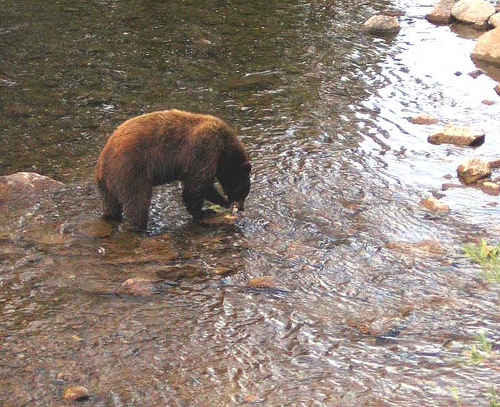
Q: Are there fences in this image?
A: No, there are no fences.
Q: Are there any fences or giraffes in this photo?
A: No, there are no fences or giraffes.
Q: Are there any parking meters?
A: No, there are no parking meters.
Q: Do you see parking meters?
A: No, there are no parking meters.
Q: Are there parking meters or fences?
A: No, there are no parking meters or fences.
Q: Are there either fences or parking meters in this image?
A: No, there are no parking meters or fences.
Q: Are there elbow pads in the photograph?
A: No, there are no elbow pads.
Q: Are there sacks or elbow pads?
A: No, there are no elbow pads or sacks.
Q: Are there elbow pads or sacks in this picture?
A: No, there are no elbow pads or sacks.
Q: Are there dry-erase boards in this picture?
A: No, there are no dry-erase boards.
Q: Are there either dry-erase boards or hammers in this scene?
A: No, there are no dry-erase boards or hammers.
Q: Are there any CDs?
A: No, there are no cds.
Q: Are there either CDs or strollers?
A: No, there are no CDs or strollers.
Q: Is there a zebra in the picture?
A: No, there are no zebras.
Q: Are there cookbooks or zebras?
A: No, there are no zebras or cookbooks.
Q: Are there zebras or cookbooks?
A: No, there are no zebras or cookbooks.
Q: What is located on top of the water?
A: The rock is on top of the water.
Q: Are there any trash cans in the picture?
A: No, there are no trash cans.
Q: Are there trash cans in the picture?
A: No, there are no trash cans.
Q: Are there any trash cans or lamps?
A: No, there are no trash cans or lamps.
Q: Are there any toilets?
A: No, there are no toilets.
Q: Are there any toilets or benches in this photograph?
A: No, there are no toilets or benches.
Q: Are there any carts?
A: No, there are no carts.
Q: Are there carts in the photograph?
A: No, there are no carts.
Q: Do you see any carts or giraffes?
A: No, there are no carts or giraffes.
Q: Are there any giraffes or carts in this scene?
A: No, there are no carts or giraffes.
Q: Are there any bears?
A: Yes, there is a bear.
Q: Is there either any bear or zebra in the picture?
A: Yes, there is a bear.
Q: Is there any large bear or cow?
A: Yes, there is a large bear.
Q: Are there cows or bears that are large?
A: Yes, the bear is large.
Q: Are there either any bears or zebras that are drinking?
A: Yes, the bear is drinking.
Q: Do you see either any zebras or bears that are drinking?
A: Yes, the bear is drinking.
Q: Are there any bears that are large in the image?
A: Yes, there is a large bear.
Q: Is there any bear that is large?
A: Yes, there is a bear that is large.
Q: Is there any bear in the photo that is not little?
A: Yes, there is a large bear.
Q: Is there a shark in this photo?
A: No, there are no sharks.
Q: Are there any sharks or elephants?
A: No, there are no sharks or elephants.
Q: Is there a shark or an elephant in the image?
A: No, there are no sharks or elephants.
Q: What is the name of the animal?
A: The animal is a bear.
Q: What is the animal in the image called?
A: The animal is a bear.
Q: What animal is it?
A: The animal is a bear.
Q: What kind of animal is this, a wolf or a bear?
A: This is a bear.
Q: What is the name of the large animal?
A: The animal is a bear.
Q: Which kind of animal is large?
A: The animal is a bear.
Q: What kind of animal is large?
A: The animal is a bear.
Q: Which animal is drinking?
A: The animal is a bear.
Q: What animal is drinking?
A: The animal is a bear.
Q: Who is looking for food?
A: The bear is looking for food.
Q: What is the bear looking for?
A: The bear is looking for food.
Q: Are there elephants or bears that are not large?
A: No, there is a bear but it is large.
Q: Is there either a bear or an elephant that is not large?
A: No, there is a bear but it is large.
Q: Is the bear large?
A: Yes, the bear is large.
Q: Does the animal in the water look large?
A: Yes, the bear is large.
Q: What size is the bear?
A: The bear is large.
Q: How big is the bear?
A: The bear is large.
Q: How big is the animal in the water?
A: The bear is large.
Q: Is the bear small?
A: No, the bear is large.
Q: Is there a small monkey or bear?
A: No, there is a bear but it is large.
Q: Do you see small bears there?
A: No, there is a bear but it is large.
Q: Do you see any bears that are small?
A: No, there is a bear but it is large.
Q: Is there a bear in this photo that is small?
A: No, there is a bear but it is large.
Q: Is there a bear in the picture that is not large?
A: No, there is a bear but it is large.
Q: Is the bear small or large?
A: The bear is large.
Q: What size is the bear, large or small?
A: The bear is large.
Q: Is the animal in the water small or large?
A: The bear is large.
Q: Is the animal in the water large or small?
A: The bear is large.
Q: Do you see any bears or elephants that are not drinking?
A: No, there is a bear but it is drinking.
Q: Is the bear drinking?
A: Yes, the bear is drinking.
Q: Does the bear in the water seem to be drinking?
A: Yes, the bear is drinking.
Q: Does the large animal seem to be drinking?
A: Yes, the bear is drinking.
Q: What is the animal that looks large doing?
A: The bear is drinking.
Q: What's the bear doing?
A: The bear is drinking.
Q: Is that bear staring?
A: No, the bear is drinking.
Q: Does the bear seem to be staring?
A: No, the bear is drinking.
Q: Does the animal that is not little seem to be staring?
A: No, the bear is drinking.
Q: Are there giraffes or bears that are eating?
A: No, there is a bear but it is drinking.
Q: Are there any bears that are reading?
A: No, there is a bear but it is drinking.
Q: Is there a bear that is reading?
A: No, there is a bear but it is drinking.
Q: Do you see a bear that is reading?
A: No, there is a bear but it is drinking.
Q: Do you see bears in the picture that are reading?
A: No, there is a bear but it is drinking.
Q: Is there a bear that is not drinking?
A: No, there is a bear but it is drinking.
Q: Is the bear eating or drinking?
A: The bear is drinking.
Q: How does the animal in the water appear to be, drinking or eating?
A: The bear is drinking.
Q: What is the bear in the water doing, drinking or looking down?
A: The bear is drinking.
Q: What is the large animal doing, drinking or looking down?
A: The bear is drinking.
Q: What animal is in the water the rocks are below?
A: The bear is in the water.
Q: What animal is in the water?
A: The bear is in the water.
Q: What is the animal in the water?
A: The animal is a bear.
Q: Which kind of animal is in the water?
A: The animal is a bear.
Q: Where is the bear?
A: The bear is in the water.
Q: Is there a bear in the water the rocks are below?
A: Yes, there is a bear in the water.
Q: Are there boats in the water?
A: No, there is a bear in the water.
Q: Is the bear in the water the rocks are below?
A: Yes, the bear is in the water.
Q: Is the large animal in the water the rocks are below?
A: Yes, the bear is in the water.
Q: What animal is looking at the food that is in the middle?
A: The bear is looking at the food.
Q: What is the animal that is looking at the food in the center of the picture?
A: The animal is a bear.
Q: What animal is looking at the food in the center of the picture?
A: The animal is a bear.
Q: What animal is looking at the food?
A: The animal is a bear.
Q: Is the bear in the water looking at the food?
A: Yes, the bear is looking at the food.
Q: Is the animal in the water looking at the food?
A: Yes, the bear is looking at the food.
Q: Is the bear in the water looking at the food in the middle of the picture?
A: Yes, the bear is looking at the food.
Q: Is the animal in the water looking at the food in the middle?
A: Yes, the bear is looking at the food.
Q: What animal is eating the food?
A: The bear is eating the food.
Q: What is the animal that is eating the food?
A: The animal is a bear.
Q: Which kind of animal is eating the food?
A: The animal is a bear.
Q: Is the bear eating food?
A: Yes, the bear is eating food.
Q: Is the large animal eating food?
A: Yes, the bear is eating food.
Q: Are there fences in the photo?
A: No, there are no fences.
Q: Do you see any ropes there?
A: No, there are no ropes.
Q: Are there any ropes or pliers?
A: No, there are no ropes or pliers.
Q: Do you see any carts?
A: No, there are no carts.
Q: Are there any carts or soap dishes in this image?
A: No, there are no carts or soap dishes.